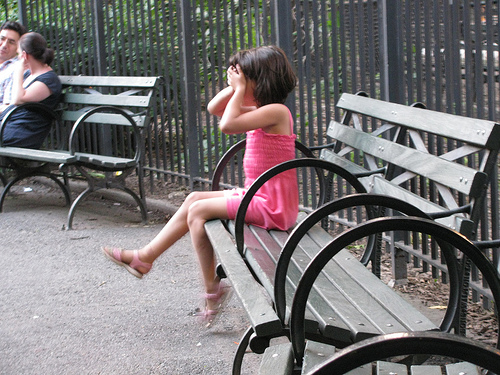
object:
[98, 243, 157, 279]
pink shoes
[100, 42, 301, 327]
kid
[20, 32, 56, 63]
hair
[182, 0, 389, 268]
fence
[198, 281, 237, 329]
sandals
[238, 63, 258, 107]
face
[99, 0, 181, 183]
fence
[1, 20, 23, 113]
man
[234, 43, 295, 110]
dark hair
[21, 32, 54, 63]
dark hair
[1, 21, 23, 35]
dark hair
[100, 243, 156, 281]
sandals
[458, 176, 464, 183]
bolt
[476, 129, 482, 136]
bolt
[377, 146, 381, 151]
bolt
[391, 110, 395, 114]
bolt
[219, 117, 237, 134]
elbow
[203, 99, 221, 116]
elbow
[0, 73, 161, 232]
bench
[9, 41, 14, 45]
eyes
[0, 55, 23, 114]
white shirt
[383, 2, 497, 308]
fencing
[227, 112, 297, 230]
dress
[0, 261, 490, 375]
ground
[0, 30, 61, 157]
woman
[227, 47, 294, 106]
hair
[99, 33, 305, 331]
girl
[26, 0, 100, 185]
fencing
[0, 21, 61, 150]
couple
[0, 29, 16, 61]
face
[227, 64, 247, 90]
hand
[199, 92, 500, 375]
bench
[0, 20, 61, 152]
man/woman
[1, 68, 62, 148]
black dress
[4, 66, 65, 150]
top